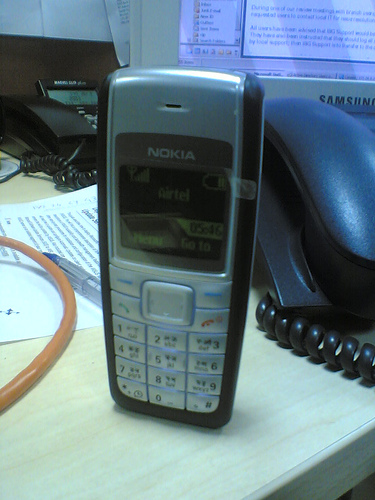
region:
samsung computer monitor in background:
[132, 0, 372, 70]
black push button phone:
[1, 71, 96, 180]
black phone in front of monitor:
[266, 97, 373, 311]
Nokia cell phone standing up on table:
[103, 70, 259, 426]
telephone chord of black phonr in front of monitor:
[252, 310, 373, 380]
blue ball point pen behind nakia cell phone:
[42, 250, 99, 302]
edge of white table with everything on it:
[238, 421, 371, 498]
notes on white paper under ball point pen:
[2, 201, 95, 250]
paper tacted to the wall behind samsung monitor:
[104, 1, 128, 64]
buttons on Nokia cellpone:
[115, 319, 219, 411]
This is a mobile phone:
[68, 56, 288, 453]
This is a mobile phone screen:
[113, 152, 234, 285]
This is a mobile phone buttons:
[107, 263, 231, 420]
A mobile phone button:
[101, 261, 148, 297]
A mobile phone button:
[141, 276, 203, 330]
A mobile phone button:
[192, 280, 233, 311]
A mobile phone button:
[187, 303, 229, 333]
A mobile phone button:
[106, 314, 153, 340]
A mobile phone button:
[143, 323, 192, 345]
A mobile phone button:
[188, 328, 233, 352]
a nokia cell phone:
[94, 62, 261, 429]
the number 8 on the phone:
[146, 366, 185, 392]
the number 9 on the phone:
[186, 372, 222, 395]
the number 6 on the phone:
[185, 352, 225, 372]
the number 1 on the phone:
[111, 316, 145, 340]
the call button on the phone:
[106, 289, 142, 322]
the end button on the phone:
[186, 307, 231, 332]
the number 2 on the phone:
[146, 324, 187, 350]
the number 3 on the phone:
[189, 332, 227, 351]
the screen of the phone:
[109, 155, 236, 278]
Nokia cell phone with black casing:
[95, 63, 268, 433]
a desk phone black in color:
[1, 76, 103, 186]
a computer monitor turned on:
[132, 0, 374, 68]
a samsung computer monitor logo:
[255, 72, 373, 106]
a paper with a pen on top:
[1, 197, 103, 333]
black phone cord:
[250, 291, 373, 382]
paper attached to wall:
[76, 0, 129, 66]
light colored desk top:
[1, 425, 374, 497]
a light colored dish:
[0, 155, 20, 184]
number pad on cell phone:
[107, 309, 236, 422]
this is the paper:
[1, 269, 32, 294]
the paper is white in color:
[4, 275, 34, 292]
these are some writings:
[18, 211, 95, 236]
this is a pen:
[39, 247, 103, 304]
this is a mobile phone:
[95, 62, 262, 422]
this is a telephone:
[269, 97, 374, 316]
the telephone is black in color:
[267, 101, 342, 158]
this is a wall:
[8, 59, 29, 80]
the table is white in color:
[152, 458, 231, 496]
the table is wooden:
[95, 430, 171, 478]